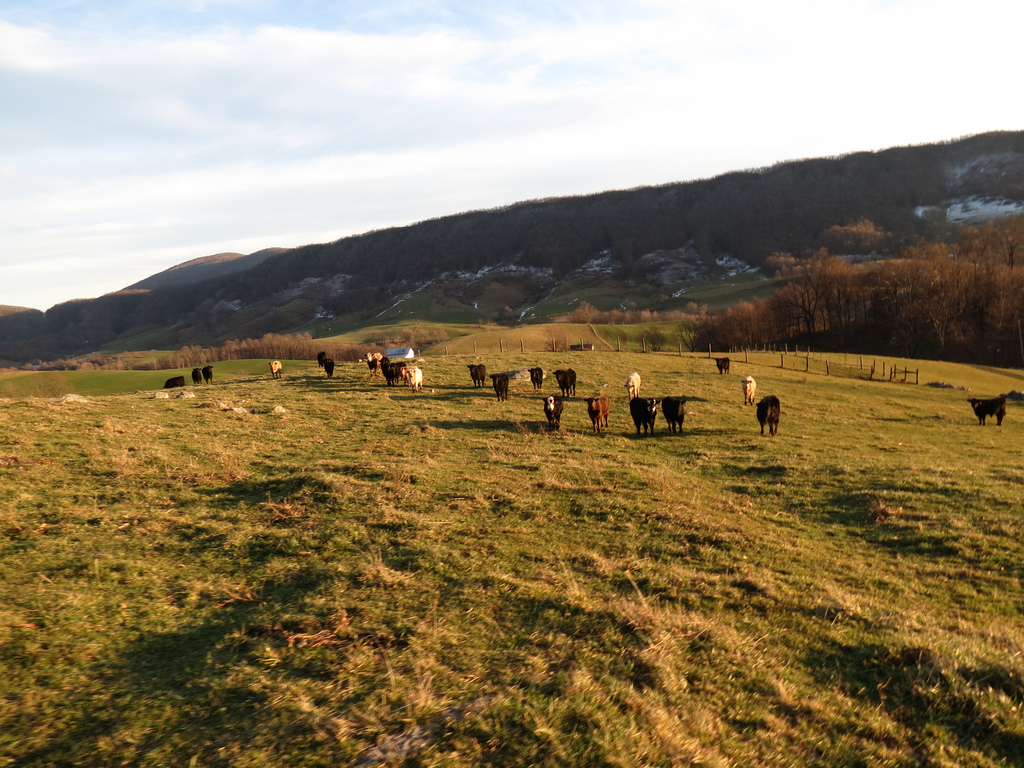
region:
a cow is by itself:
[969, 375, 1014, 452]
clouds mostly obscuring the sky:
[38, 10, 687, 184]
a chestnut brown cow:
[582, 389, 612, 438]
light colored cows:
[618, 371, 780, 403]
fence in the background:
[648, 326, 920, 388]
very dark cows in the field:
[623, 393, 792, 442]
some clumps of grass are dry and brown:
[619, 609, 686, 692]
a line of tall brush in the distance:
[123, 329, 355, 371]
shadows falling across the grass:
[114, 593, 269, 746]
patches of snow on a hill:
[404, 247, 765, 337]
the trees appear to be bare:
[733, 233, 1022, 363]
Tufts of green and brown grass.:
[89, 478, 868, 734]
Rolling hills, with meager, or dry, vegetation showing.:
[7, 118, 1004, 330]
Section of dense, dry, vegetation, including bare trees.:
[678, 243, 1010, 395]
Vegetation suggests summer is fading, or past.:
[408, 161, 985, 525]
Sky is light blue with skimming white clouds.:
[67, 6, 598, 228]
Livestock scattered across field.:
[191, 332, 1021, 440]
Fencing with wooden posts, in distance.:
[708, 326, 1004, 441]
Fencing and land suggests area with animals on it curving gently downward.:
[197, 330, 1022, 546]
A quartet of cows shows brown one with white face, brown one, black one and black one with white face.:
[506, 386, 688, 458]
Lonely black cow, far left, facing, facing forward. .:
[955, 377, 1020, 428]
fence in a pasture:
[745, 329, 952, 399]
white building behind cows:
[351, 328, 438, 398]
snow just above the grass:
[569, 230, 784, 317]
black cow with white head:
[511, 377, 581, 453]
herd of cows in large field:
[63, 336, 1013, 597]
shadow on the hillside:
[100, 212, 313, 307]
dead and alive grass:
[142, 458, 822, 673]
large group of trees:
[730, 247, 1019, 345]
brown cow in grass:
[563, 376, 633, 452]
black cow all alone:
[907, 354, 1019, 462]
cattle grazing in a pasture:
[316, 358, 1009, 436]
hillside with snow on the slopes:
[571, 136, 1014, 337]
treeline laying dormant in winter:
[675, 237, 1009, 370]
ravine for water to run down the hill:
[501, 260, 575, 325]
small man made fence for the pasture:
[764, 355, 920, 385]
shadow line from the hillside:
[88, 285, 766, 378]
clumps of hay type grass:
[586, 604, 755, 700]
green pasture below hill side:
[22, 348, 329, 410]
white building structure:
[375, 329, 432, 369]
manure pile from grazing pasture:
[340, 689, 490, 766]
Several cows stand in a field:
[120, 324, 1005, 467]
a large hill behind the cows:
[46, 217, 1021, 348]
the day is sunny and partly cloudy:
[35, 112, 690, 325]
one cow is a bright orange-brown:
[575, 386, 617, 444]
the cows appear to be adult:
[147, 327, 1023, 509]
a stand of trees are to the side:
[675, 213, 1023, 388]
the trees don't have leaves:
[694, 229, 1023, 372]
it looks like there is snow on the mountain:
[202, 206, 854, 308]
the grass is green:
[79, 441, 997, 761]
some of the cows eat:
[135, 343, 325, 476]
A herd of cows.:
[149, 353, 1017, 427]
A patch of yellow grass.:
[457, 447, 676, 502]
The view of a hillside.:
[359, 274, 789, 310]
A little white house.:
[384, 346, 441, 363]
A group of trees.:
[729, 229, 993, 376]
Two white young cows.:
[582, 355, 773, 397]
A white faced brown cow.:
[531, 370, 569, 446]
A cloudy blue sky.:
[76, 1, 412, 110]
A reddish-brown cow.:
[578, 393, 630, 455]